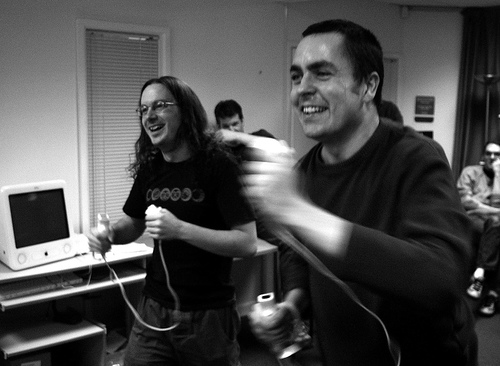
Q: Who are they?
A: People.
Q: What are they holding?
A: Console.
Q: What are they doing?
A: Playing.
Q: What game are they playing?
A: Wii.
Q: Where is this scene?
A: In a play room.